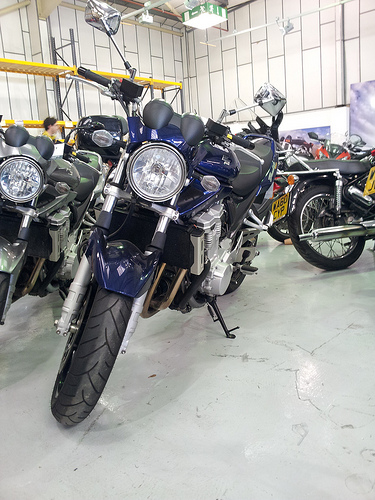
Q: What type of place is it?
A: It is a shop.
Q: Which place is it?
A: It is a shop.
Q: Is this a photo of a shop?
A: Yes, it is showing a shop.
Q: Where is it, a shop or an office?
A: It is a shop.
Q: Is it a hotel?
A: No, it is a shop.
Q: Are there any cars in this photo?
A: No, there are no cars.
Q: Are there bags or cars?
A: No, there are no cars or bags.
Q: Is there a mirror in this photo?
A: Yes, there is a mirror.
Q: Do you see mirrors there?
A: Yes, there is a mirror.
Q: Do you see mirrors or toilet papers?
A: Yes, there is a mirror.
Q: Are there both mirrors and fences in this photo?
A: No, there is a mirror but no fences.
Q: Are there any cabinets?
A: No, there are no cabinets.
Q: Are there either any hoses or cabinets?
A: No, there are no cabinets or hoses.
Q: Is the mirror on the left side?
A: Yes, the mirror is on the left of the image.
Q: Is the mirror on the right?
A: No, the mirror is on the left of the image.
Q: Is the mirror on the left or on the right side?
A: The mirror is on the left of the image.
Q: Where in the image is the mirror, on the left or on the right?
A: The mirror is on the left of the image.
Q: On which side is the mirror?
A: The mirror is on the left of the image.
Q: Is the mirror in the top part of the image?
A: Yes, the mirror is in the top of the image.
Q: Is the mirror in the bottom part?
A: No, the mirror is in the top of the image.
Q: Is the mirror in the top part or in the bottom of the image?
A: The mirror is in the top of the image.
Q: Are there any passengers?
A: No, there are no passengers.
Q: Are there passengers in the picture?
A: No, there are no passengers.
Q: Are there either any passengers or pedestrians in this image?
A: No, there are no passengers or pedestrians.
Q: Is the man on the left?
A: Yes, the man is on the left of the image.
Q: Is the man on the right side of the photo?
A: No, the man is on the left of the image.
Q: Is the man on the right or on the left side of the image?
A: The man is on the left of the image.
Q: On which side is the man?
A: The man is on the left of the image.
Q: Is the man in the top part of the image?
A: Yes, the man is in the top of the image.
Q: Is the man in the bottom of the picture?
A: No, the man is in the top of the image.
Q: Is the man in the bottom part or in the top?
A: The man is in the top of the image.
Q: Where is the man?
A: The man is in the shop.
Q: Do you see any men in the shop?
A: Yes, there is a man in the shop.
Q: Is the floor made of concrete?
A: Yes, the floor is made of concrete.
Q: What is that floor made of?
A: The floor is made of cement.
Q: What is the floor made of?
A: The floor is made of concrete.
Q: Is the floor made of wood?
A: No, the floor is made of cement.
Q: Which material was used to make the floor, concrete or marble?
A: The floor is made of concrete.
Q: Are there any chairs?
A: No, there are no chairs.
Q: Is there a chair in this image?
A: No, there are no chairs.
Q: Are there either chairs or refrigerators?
A: No, there are no chairs or refrigerators.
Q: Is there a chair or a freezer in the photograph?
A: No, there are no chairs or refrigerators.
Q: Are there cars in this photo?
A: No, there are no cars.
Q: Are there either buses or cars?
A: No, there are no cars or buses.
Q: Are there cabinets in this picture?
A: No, there are no cabinets.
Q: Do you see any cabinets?
A: No, there are no cabinets.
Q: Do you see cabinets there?
A: No, there are no cabinets.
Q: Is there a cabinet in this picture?
A: No, there are no cabinets.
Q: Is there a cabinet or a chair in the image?
A: No, there are no cabinets or chairs.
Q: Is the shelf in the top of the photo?
A: Yes, the shelf is in the top of the image.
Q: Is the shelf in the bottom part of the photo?
A: No, the shelf is in the top of the image.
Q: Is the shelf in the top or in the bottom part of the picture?
A: The shelf is in the top of the image.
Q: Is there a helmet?
A: No, there are no helmets.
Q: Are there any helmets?
A: No, there are no helmets.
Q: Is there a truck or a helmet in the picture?
A: No, there are no helmets or trucks.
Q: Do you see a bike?
A: Yes, there is a bike.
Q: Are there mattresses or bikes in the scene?
A: Yes, there is a bike.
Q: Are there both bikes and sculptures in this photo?
A: No, there is a bike but no sculptures.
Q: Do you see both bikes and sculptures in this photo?
A: No, there is a bike but no sculptures.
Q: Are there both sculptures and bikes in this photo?
A: No, there is a bike but no sculptures.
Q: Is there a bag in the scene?
A: No, there are no bags.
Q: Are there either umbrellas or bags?
A: No, there are no bags or umbrellas.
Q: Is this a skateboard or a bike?
A: This is a bike.